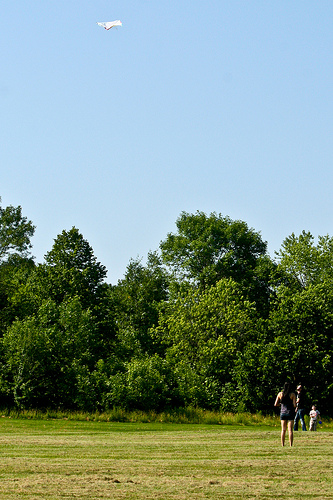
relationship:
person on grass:
[274, 382, 298, 448] [2, 415, 332, 499]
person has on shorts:
[274, 382, 298, 448] [280, 408, 295, 422]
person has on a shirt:
[274, 382, 298, 448] [280, 392, 295, 415]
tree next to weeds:
[1, 194, 332, 415] [3, 408, 329, 423]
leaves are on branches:
[3, 205, 330, 412] [160, 255, 200, 298]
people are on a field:
[276, 384, 312, 445] [2, 416, 332, 499]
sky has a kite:
[3, 6, 332, 288] [97, 18, 120, 30]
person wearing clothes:
[278, 386, 295, 444] [277, 394, 296, 422]